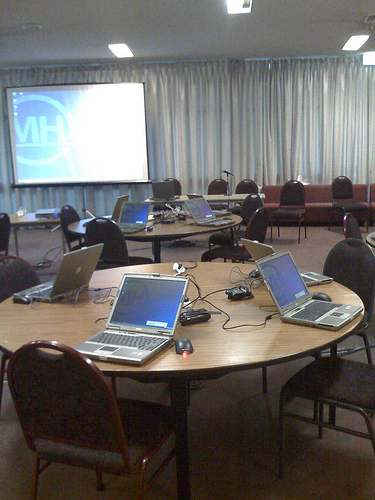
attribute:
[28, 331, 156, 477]
chair — conference, gray, red, here, padded , metal , present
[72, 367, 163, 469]
metal — here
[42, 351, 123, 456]
padding — here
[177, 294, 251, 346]
mouse — computer, black, wired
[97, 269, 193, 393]
laptop — gray, open, here, computer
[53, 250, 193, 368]
computer — closed, here, open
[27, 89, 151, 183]
screen — large, up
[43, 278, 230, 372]
table — round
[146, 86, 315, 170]
curtain — white, closed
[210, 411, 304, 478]
floor — brown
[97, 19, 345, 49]
lights — on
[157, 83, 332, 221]
curtains — white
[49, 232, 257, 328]
laptops — grey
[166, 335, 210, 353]
light — red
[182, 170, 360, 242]
chairs — around, many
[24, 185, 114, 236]
microphone — on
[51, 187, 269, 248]
computers — silver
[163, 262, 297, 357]
wires — few